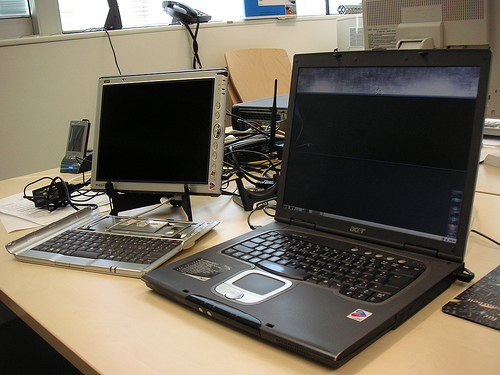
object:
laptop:
[141, 49, 494, 370]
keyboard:
[219, 230, 427, 303]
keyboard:
[30, 228, 184, 264]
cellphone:
[64, 119, 91, 160]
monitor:
[88, 67, 227, 197]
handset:
[161, 0, 211, 23]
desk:
[0, 124, 499, 374]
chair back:
[223, 46, 292, 103]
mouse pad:
[441, 265, 500, 331]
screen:
[93, 76, 214, 186]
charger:
[59, 150, 93, 174]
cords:
[22, 111, 286, 230]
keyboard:
[483, 118, 500, 137]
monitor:
[362, 1, 499, 120]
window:
[58, 0, 363, 34]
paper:
[1, 184, 112, 234]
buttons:
[214, 101, 221, 169]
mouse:
[215, 270, 293, 304]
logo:
[346, 308, 373, 322]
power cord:
[22, 176, 105, 213]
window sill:
[1, 12, 362, 49]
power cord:
[456, 267, 475, 283]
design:
[441, 263, 500, 330]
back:
[357, 2, 499, 116]